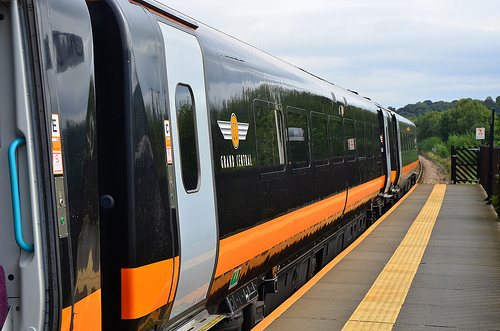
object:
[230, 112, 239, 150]
circle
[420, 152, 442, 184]
dirt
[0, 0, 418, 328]
train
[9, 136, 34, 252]
handle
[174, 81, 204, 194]
window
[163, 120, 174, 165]
sign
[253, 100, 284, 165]
window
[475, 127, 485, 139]
sign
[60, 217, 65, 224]
button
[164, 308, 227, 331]
step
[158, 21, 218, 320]
door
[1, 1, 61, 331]
door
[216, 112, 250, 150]
logo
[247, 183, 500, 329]
loading area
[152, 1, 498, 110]
sky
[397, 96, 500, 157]
wooded area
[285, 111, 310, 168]
window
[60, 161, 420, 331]
stripe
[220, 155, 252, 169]
name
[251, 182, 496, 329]
station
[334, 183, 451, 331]
line